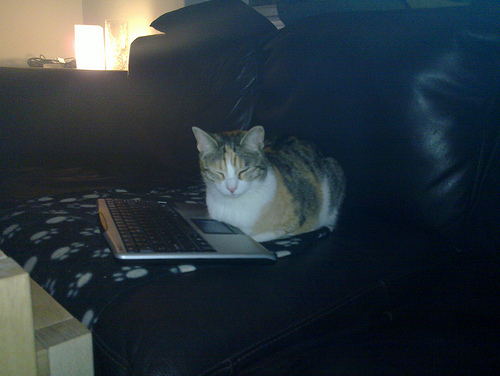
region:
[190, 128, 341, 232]
the cat is sleeping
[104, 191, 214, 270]
a laptop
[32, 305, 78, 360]
a box that is brown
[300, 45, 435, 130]
the sofa is black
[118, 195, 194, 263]
a keyboard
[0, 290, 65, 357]
the box is brown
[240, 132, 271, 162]
cat ears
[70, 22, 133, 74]
a light shade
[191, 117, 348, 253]
a cat laying on a couch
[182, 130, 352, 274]
a cat sleeping on a blanket on a couch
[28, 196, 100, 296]
white paw prints on the black blanket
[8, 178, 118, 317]
a black blanket on the couch cushion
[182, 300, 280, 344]
black leather upholtery of the couch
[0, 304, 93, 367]
tan wood surface of the coffe table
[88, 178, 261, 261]
a grey wirless keyboard on the couch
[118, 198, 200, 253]
black keys of the wireless keyboard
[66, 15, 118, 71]
bright white light in the corner of the room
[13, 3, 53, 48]
tan surface of the walls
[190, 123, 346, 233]
A cat is sleeping on the couch.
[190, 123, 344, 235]
A calico cat with a white chest.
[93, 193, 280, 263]
A silver and black keyboard on the couch.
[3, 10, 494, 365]
A black couch made of leather.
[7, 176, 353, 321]
A pet blanket is laying on the couch.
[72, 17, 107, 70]
A light on the end table is on.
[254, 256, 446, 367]
stitching in the couch cushion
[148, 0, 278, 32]
A black pillow on top of the couch.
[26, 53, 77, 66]
black cords are on the end table.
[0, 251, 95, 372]
wood table in front of couch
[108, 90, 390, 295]
a cat near a keyboard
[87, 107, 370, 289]
a keyboard near a cat on a couch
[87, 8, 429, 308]
a cat on a black couch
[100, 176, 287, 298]
a keyboard on a black couch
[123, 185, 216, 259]
black keys on a keyboard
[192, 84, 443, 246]
a brown and white cat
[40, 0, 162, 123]
a light near a black couch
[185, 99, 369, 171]
the ears of a cat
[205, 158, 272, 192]
the eyes of a cat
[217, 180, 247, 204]
the nose of a cat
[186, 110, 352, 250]
The cat has its eyes closed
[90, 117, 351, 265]
The cat is using the laptop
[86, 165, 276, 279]
A computer keyboard sits on the sofa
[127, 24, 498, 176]
The pillows are made of leather material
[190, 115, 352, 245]
The cat has brown, black, and white fur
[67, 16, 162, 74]
A lamp illuminates the room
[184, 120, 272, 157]
The cat's ears are pointed up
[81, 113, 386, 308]
The cat is sitting on the couch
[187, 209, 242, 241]
A keyboard touch mousepad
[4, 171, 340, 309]
A blanket is on the sofa